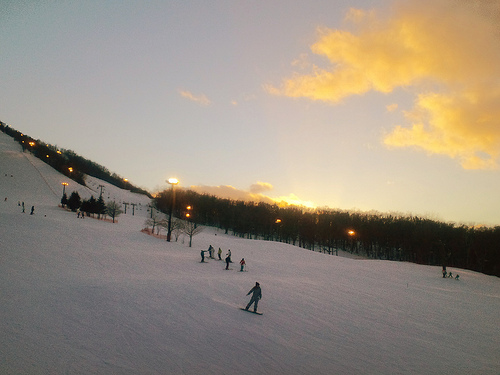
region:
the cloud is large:
[272, 18, 477, 168]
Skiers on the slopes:
[6, 230, 313, 296]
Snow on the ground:
[124, 229, 175, 311]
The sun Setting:
[229, 138, 394, 284]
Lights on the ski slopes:
[151, 149, 251, 264]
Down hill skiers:
[13, 139, 135, 293]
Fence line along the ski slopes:
[34, 156, 207, 288]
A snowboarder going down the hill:
[244, 260, 271, 320]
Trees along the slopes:
[226, 166, 447, 313]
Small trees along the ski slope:
[64, 174, 134, 255]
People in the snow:
[37, 141, 342, 371]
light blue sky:
[78, 31, 149, 76]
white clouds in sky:
[259, 0, 486, 177]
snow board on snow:
[236, 304, 263, 319]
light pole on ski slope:
[164, 174, 180, 245]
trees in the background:
[148, 186, 499, 277]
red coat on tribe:
[240, 258, 245, 264]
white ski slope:
[2, 125, 499, 373]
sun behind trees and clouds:
[296, 195, 316, 210]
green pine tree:
[94, 193, 109, 218]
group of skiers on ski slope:
[197, 240, 247, 272]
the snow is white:
[42, 222, 177, 314]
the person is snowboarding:
[226, 271, 286, 334]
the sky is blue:
[72, 20, 241, 173]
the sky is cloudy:
[65, 15, 457, 112]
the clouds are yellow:
[285, 13, 489, 197]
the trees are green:
[237, 177, 404, 279]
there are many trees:
[210, 164, 427, 261]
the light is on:
[164, 169, 185, 187]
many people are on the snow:
[164, 230, 278, 325]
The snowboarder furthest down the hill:
[240, 281, 276, 321]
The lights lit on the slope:
[27, 138, 361, 240]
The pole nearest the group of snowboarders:
[162, 176, 179, 243]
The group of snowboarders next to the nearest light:
[197, 242, 248, 276]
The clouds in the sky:
[177, 5, 497, 202]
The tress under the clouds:
[160, 188, 496, 279]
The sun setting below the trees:
[269, 189, 316, 218]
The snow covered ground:
[2, 122, 499, 374]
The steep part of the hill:
[2, 123, 145, 213]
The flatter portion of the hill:
[0, 212, 495, 373]